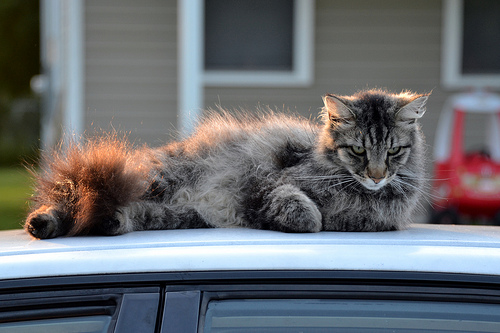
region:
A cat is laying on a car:
[16, 45, 468, 297]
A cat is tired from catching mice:
[15, 45, 485, 300]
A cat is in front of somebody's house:
[16, 45, 472, 298]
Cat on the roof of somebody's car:
[11, 53, 471, 308]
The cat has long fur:
[20, 72, 461, 294]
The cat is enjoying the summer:
[10, 60, 476, 291]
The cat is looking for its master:
[12, 55, 478, 286]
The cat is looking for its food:
[15, 62, 460, 297]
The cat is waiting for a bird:
[15, 68, 445, 300]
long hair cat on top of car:
[20, 77, 447, 252]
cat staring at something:
[310, 83, 436, 193]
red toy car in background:
[420, 83, 499, 208]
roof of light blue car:
[2, 194, 497, 286]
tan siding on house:
[25, 0, 498, 173]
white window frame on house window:
[167, 0, 326, 98]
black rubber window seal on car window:
[194, 283, 499, 332]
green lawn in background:
[1, 159, 54, 235]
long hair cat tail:
[49, 115, 136, 241]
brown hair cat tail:
[24, 123, 143, 238]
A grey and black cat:
[21, 76, 457, 247]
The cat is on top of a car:
[15, 77, 445, 329]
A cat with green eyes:
[316, 85, 441, 199]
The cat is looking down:
[315, 82, 448, 204]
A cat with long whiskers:
[281, 78, 464, 215]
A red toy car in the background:
[421, 73, 499, 235]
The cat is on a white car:
[18, 79, 468, 316]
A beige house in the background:
[45, 0, 495, 133]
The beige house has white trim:
[52, 2, 497, 122]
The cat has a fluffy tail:
[16, 112, 182, 247]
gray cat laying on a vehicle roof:
[22, 90, 432, 229]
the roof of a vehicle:
[5, 223, 499, 328]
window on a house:
[184, 0, 318, 86]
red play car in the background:
[428, 86, 499, 231]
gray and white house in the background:
[37, 2, 499, 225]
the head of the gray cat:
[321, 86, 426, 193]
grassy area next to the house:
[0, 163, 40, 227]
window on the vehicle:
[204, 291, 498, 331]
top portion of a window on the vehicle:
[1, 299, 115, 330]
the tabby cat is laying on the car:
[22, 85, 429, 240]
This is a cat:
[23, 78, 448, 249]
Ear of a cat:
[389, 68, 440, 125]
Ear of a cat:
[312, 78, 365, 135]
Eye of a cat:
[381, 138, 406, 160]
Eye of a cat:
[341, 131, 368, 158]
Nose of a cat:
[367, 162, 394, 182]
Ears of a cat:
[312, 74, 449, 127]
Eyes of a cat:
[344, 131, 416, 158]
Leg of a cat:
[264, 180, 326, 244]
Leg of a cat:
[100, 189, 204, 243]